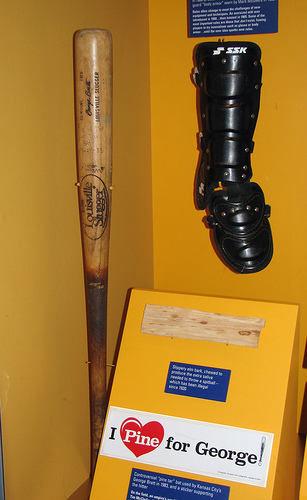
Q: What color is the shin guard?
A: Black.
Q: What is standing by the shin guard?
A: Bat.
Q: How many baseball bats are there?
A: One.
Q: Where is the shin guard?
A: On the wall.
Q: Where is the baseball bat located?
A: On wall.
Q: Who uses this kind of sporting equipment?
A: Baseball players.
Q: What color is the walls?
A: Yellow.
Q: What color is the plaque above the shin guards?
A: Blue.